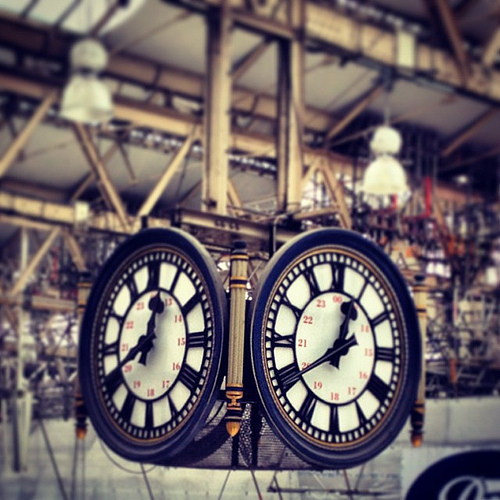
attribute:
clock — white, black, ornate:
[244, 226, 425, 474]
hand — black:
[274, 329, 363, 387]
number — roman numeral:
[323, 256, 355, 294]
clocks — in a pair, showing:
[75, 214, 435, 468]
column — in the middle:
[221, 241, 257, 449]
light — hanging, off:
[58, 27, 128, 132]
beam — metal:
[202, 14, 244, 183]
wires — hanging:
[371, 82, 435, 125]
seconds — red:
[299, 307, 310, 360]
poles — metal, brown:
[188, 56, 339, 200]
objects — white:
[46, 38, 419, 204]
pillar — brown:
[223, 230, 251, 359]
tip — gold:
[221, 413, 244, 438]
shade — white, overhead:
[362, 158, 411, 201]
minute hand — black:
[103, 330, 152, 393]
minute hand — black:
[288, 340, 360, 396]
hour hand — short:
[338, 293, 361, 346]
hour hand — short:
[132, 287, 174, 338]